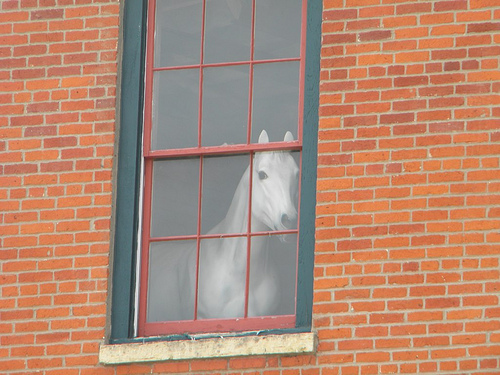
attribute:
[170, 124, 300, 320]
horse — white, looking, plastic, standing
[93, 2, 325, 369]
window — red, large, glass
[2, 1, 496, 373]
wall — brick, big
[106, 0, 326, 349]
frame — green, red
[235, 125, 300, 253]
head — white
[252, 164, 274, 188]
eye — dark, black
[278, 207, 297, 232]
nose — black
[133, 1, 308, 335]
trim — red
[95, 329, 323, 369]
window sill — concrete, tan, green, white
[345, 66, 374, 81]
brick — red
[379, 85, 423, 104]
brick — red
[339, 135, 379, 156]
brick — red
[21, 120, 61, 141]
brick — red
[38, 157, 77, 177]
brick — red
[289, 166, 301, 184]
eye — dark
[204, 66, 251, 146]
panel — glass